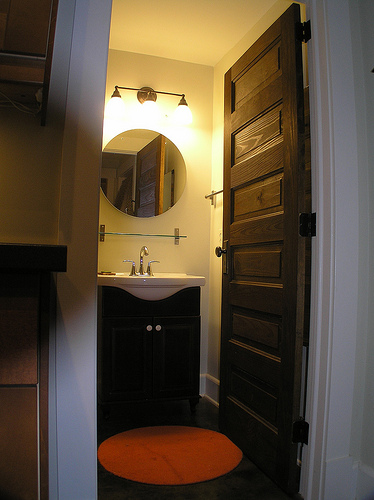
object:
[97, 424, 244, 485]
rug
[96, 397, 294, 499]
floor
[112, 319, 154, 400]
doors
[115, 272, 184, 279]
sink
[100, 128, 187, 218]
mirror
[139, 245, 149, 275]
faucet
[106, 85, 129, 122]
lights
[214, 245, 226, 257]
doorknob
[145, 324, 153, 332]
knobs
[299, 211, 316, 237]
door hinge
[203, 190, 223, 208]
towel rack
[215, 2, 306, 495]
door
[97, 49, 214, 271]
wall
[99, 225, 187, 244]
towel rack